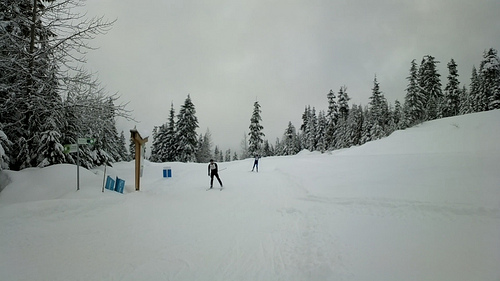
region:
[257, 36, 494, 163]
trees covered in snow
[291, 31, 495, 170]
green trees covered in snow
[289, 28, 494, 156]
evergreen trees covered in snow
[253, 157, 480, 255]
patch of white snow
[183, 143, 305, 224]
some people out in the snow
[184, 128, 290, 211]
people skiing in the snow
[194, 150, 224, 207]
person skking in the distance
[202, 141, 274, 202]
people skiing in the distance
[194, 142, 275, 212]
some people skiing off in the distance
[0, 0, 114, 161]
tall evergreen trees in snow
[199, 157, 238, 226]
Person skiing down mountain.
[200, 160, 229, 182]
Person holding ski poles.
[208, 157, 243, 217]
Person wearing dark clothing.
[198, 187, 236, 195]
Skis on person's feet.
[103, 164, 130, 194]
Blue objects in snow.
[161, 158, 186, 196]
Blue objects in snow.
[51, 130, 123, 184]
White signs attached to pole.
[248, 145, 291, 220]
Person skiing behind other person.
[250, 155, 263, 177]
Person wearing dark clothing.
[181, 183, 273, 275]
White snow on ground.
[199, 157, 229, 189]
Man skiing in snow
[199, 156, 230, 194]
Man on skis in snow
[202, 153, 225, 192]
Man in skis on snow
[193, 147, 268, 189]
Two people on ski slope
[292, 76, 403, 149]
Lots of trees covered in snow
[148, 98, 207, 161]
Pine trees covered in snow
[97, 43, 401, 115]
Clouds sky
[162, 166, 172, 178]
Blue flag behind skier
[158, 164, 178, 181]
Blue flag behind man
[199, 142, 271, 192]
Two skiers on snow covered mountain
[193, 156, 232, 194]
a person skiing on the side of a mountain.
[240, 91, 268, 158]
a very tall pine tree in the snow.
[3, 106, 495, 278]
a snow covered ski slope.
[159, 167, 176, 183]
a flag on the side of a snow covered slope.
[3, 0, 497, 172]
a forest filled with pine trees.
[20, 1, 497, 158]
a cloudy gray sky.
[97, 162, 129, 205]
a flag area.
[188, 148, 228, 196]
a person in winter clothing.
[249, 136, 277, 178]
a human on skis.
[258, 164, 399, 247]
tracks in the snow.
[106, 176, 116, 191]
light blue and white sign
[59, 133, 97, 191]
green and white direction signs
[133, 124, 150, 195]
wood billboard with maps on it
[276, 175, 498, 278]
snow with ski tracks in it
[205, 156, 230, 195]
skier with pole extended behind them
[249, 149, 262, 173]
skier on flat land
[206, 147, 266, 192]
skiers skiing down lane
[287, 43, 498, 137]
snow capped trees on hill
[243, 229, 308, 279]
tracks in the snow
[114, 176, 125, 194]
second blue and white sign